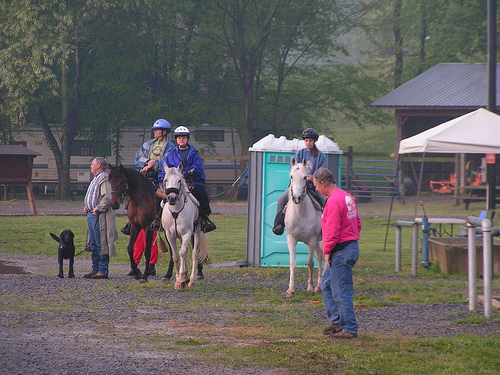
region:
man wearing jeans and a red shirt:
[313, 170, 370, 335]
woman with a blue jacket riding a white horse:
[163, 130, 216, 289]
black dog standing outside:
[48, 230, 74, 275]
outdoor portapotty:
[246, 135, 275, 264]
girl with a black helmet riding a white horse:
[286, 123, 317, 280]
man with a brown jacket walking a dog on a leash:
[51, 156, 113, 278]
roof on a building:
[368, 62, 483, 108]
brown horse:
[110, 160, 150, 225]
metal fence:
[347, 155, 393, 192]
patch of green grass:
[368, 345, 490, 372]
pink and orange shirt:
[313, 188, 366, 263]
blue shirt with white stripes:
[77, 174, 116, 214]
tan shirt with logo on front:
[138, 141, 173, 163]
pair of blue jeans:
[311, 245, 386, 350]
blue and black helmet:
[298, 125, 328, 140]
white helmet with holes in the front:
[166, 123, 198, 143]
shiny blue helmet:
[142, 108, 173, 133]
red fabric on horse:
[121, 222, 171, 270]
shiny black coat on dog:
[48, 216, 85, 271]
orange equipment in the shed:
[423, 155, 490, 197]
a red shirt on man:
[310, 183, 370, 267]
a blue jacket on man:
[141, 137, 226, 180]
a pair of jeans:
[319, 242, 378, 329]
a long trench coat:
[93, 172, 118, 260]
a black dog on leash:
[30, 223, 100, 281]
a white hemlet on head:
[171, 123, 191, 137]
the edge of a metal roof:
[363, 49, 488, 111]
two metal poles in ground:
[456, 203, 495, 330]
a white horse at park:
[273, 156, 336, 302]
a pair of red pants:
[120, 231, 167, 277]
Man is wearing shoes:
[322, 321, 361, 338]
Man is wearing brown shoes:
[322, 316, 358, 339]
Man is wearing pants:
[320, 240, 362, 330]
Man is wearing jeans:
[317, 240, 357, 331]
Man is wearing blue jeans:
[320, 237, 357, 329]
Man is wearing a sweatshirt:
[320, 185, 360, 250]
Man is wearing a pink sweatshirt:
[315, 187, 362, 252]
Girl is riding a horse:
[274, 123, 339, 298]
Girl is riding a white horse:
[272, 125, 357, 298]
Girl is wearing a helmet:
[295, 125, 321, 140]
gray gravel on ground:
[56, 296, 122, 336]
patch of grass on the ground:
[314, 342, 406, 359]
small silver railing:
[383, 208, 435, 279]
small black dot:
[41, 220, 88, 277]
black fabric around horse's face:
[153, 182, 208, 211]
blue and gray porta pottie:
[240, 133, 350, 288]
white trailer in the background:
[6, 103, 261, 213]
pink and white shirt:
[302, 193, 378, 246]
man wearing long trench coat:
[76, 177, 133, 260]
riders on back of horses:
[71, 105, 377, 282]